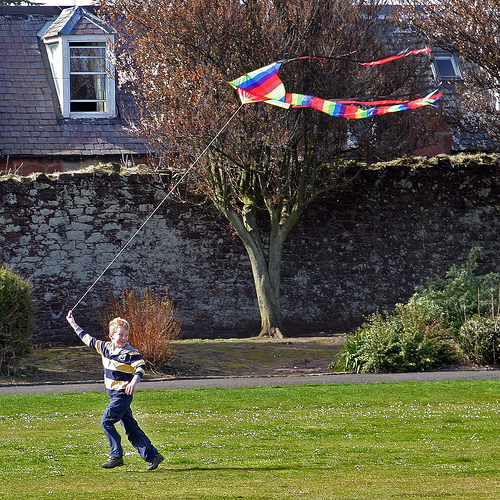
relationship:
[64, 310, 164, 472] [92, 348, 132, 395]
boy on shirt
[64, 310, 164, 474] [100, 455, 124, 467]
boy wearing black shoe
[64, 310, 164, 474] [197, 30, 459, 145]
boy flying kite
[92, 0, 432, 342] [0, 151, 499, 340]
tree near stone wall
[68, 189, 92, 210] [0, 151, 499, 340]
rock near stone wall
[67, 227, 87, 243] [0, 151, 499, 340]
grey rock on stone wall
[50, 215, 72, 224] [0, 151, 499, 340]
rock on stone wall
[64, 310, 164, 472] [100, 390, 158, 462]
boy wearing jeans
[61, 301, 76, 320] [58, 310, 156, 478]
hand of boy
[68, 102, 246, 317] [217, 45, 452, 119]
string of kite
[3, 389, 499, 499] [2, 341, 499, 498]
grass in field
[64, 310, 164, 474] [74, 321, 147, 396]
boy in shirt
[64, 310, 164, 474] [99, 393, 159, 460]
boy in jeans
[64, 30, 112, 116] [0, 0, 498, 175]
window in house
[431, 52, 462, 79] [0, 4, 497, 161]
skylight on roof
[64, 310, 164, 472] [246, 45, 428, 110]
boy holding kite